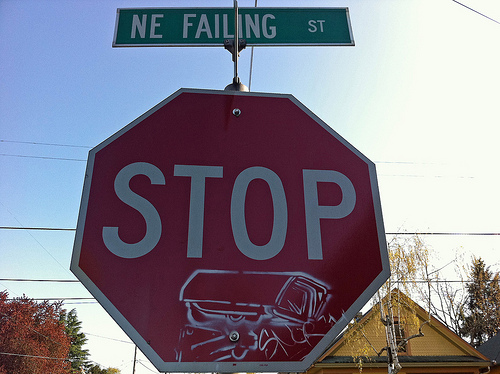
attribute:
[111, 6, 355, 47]
street name sign — here, green, white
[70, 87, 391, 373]
stop sign — octagonal, big, traffic signal, white bordered, close up, white worded, here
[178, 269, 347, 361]
graffiti — white, small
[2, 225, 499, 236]
electrical wire — overhead, thin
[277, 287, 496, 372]
home — yellow, here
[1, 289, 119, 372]
trees — beautiful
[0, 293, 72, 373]
leaves — gold, red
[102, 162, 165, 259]
s — printed, white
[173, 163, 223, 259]
t — white, printed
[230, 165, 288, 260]
o — printed, white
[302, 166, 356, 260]
p — white, printed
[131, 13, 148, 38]
n — printed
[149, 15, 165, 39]
e — printed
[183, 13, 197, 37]
f — printed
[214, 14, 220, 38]
i — printed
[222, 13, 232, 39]
l — printed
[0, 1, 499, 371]
sky — blue color, sunny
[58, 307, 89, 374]
tree — green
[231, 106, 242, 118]
screw — silver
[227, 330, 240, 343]
bolt — silver